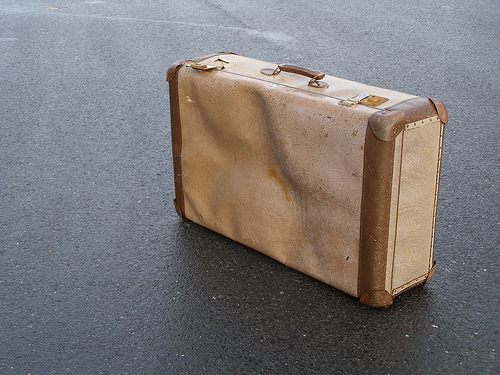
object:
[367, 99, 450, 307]
trim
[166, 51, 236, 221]
trim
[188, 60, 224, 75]
tear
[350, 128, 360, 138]
spots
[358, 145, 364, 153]
spots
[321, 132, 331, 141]
spots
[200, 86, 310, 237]
dent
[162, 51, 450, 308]
brown suitcase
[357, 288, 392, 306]
corner protector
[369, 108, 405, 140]
corner protector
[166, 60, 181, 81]
corner protector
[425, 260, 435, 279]
corner protector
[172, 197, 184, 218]
corner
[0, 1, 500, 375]
ground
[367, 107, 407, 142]
protector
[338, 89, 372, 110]
clasp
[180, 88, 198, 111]
mark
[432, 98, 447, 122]
corner protector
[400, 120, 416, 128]
rivets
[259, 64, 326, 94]
hand